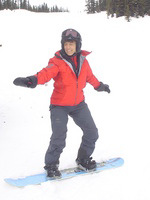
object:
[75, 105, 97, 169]
leg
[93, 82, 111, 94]
hand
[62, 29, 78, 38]
goggles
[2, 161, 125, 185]
snowboard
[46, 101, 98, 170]
pants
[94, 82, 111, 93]
gloves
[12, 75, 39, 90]
hands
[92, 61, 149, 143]
snow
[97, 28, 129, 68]
snow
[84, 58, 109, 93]
arm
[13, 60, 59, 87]
arm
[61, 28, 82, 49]
helmet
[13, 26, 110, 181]
person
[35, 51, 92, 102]
jacket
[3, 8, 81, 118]
white snow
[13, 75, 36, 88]
glove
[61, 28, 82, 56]
head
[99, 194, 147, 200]
white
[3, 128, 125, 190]
snowboarding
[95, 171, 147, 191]
snow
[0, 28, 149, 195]
ground